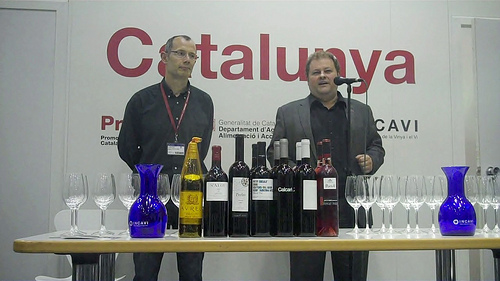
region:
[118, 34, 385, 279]
the two men standing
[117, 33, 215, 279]
the taller man standing on the left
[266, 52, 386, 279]
the shorter man standing on the right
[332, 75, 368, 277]
the microphone on the stand in front of the man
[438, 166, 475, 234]
the blue vase at the right of the table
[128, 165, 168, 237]
the blue vase at the left of the table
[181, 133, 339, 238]
the tall bottles in front of the men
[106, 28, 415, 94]
the red letters behind the men's head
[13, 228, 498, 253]
the table in front of the men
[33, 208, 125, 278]
the white chair behind the table and next to the man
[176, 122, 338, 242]
wine bottles on the table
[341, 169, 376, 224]
empty wine glasses on table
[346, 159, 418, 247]
empty wine glasses on table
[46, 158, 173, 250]
empty wine glasses on table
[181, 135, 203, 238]
bottle of wine on table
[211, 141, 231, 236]
bottle of wine on table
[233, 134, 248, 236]
bottle of wine on table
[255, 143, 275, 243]
bottle of wine on table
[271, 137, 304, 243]
bottle of wine on table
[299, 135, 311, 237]
bottle of wine on table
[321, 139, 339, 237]
bottle of wine on table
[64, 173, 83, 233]
wine glass on table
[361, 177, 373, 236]
wine glass on table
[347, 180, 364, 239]
wine glass on table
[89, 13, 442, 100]
catalunya red sign on wall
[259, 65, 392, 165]
man with gray and black suit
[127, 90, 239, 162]
black dress shirt with white buttons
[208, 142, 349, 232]
multiple wine bottles on table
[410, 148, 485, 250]
blue vase on table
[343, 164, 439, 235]
wine glasses on table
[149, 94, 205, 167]
red landyard on man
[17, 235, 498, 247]
wooden light frame on table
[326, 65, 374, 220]
black microphone on stand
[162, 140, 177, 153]
white and black ID tag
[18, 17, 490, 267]
Wine tasting time.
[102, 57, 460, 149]
Two men are standing.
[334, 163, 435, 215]
Empty wine glasses.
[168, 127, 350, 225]
Various bottles of wine.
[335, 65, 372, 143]
A microphone next to the man's face.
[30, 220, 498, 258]
A long table with legs.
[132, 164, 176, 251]
A blue vask on the table.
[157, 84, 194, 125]
Red lanyard around the man's neck.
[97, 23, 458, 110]
Red letters behind the men.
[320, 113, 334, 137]
The man is wearing a black shirt.